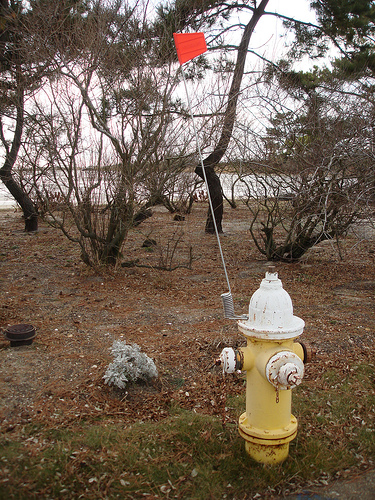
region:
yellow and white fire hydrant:
[216, 264, 315, 457]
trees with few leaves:
[66, 67, 355, 269]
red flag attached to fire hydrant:
[170, 24, 238, 339]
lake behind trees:
[7, 152, 348, 217]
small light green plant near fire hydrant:
[94, 325, 168, 401]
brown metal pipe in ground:
[6, 320, 40, 360]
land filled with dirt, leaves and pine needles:
[24, 208, 339, 309]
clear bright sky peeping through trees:
[243, 11, 298, 67]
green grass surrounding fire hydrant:
[189, 449, 245, 493]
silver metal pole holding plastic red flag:
[175, 26, 243, 331]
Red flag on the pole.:
[158, 32, 231, 90]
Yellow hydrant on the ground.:
[205, 279, 308, 498]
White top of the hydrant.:
[226, 265, 331, 344]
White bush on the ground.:
[77, 317, 216, 431]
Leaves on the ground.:
[311, 403, 364, 477]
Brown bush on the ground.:
[37, 190, 223, 300]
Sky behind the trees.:
[49, 18, 358, 154]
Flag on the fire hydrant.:
[156, 25, 286, 362]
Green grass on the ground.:
[115, 375, 191, 498]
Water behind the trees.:
[41, 156, 260, 237]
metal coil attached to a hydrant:
[196, 271, 253, 338]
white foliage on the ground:
[70, 324, 172, 400]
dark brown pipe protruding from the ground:
[3, 311, 56, 358]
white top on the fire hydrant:
[224, 253, 315, 339]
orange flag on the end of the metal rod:
[151, 19, 232, 75]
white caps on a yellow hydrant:
[207, 331, 323, 392]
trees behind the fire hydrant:
[3, 2, 361, 273]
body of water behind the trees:
[0, 158, 338, 224]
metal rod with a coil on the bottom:
[171, 53, 245, 327]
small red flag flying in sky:
[167, 26, 208, 65]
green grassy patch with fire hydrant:
[4, 345, 374, 495]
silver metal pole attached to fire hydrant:
[181, 65, 272, 323]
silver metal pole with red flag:
[170, 28, 269, 318]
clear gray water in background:
[4, 151, 361, 213]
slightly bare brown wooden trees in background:
[4, 0, 373, 281]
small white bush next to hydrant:
[99, 333, 166, 398]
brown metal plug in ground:
[2, 317, 43, 350]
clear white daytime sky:
[20, 0, 374, 172]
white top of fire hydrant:
[238, 264, 309, 336]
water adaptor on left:
[212, 345, 245, 374]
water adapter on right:
[300, 340, 319, 362]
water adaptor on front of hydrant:
[265, 346, 305, 391]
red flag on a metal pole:
[172, 28, 250, 322]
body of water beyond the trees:
[1, 161, 363, 209]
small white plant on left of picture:
[103, 335, 158, 390]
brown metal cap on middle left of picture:
[4, 320, 39, 346]